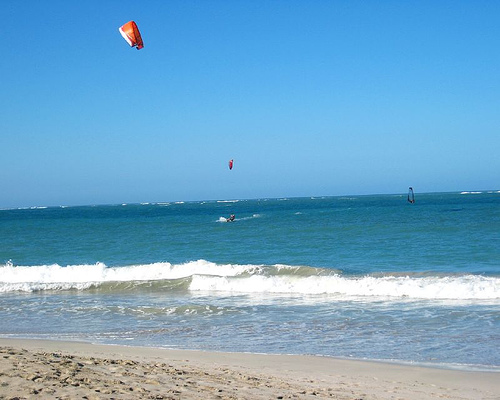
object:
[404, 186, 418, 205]
vessel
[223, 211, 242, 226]
kite surfer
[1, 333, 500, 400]
beach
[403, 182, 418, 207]
person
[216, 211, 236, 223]
motorboat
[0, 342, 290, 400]
sand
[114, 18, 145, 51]
kite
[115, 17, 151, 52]
stripe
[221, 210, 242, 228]
man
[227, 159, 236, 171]
parasail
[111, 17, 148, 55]
parasail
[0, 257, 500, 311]
wave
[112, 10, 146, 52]
kite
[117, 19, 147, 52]
balloon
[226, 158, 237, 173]
balloon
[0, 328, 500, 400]
tracks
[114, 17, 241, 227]
parasails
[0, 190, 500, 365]
blue water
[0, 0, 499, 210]
sky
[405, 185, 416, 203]
bouey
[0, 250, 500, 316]
crashing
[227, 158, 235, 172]
kite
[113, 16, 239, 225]
kitesurfing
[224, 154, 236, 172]
kitesurfing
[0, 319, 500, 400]
coast line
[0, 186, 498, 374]
water